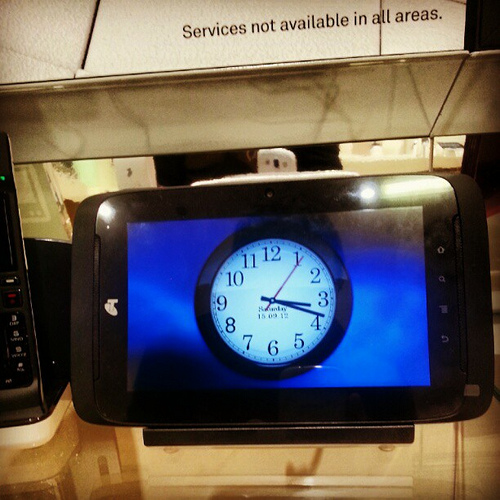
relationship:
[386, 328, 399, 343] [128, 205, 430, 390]
part of screen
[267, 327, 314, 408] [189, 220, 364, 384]
part of clock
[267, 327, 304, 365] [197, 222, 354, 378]
part of clock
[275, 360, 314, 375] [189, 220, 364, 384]
edge of clock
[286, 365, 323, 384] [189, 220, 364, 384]
edge of clock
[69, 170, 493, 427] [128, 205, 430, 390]
edge of screen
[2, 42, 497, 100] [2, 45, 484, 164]
ceiling edge lining ceiling